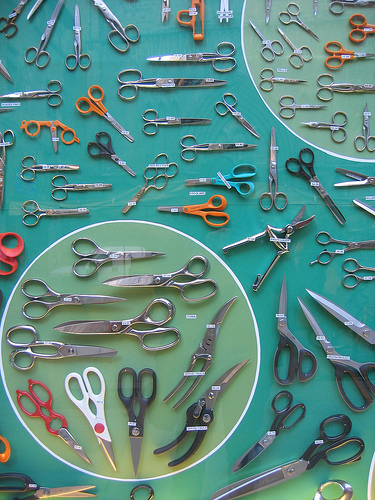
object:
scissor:
[177, 133, 257, 164]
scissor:
[113, 63, 228, 107]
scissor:
[87, 0, 143, 56]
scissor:
[86, 132, 137, 179]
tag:
[217, 169, 231, 192]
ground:
[324, 113, 325, 136]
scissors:
[101, 253, 219, 304]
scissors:
[47, 173, 113, 202]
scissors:
[20, 195, 89, 227]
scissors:
[66, 236, 168, 280]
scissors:
[258, 126, 289, 217]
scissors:
[19, 118, 79, 154]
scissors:
[18, 154, 80, 182]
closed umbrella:
[150, 191, 230, 231]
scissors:
[140, 107, 209, 141]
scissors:
[116, 64, 234, 102]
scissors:
[159, 294, 236, 413]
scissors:
[213, 90, 261, 141]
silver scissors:
[332, 164, 375, 197]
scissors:
[72, 83, 135, 145]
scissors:
[19, 112, 80, 155]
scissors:
[322, 35, 375, 73]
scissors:
[256, 115, 287, 215]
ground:
[320, 125, 349, 168]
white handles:
[82, 363, 113, 410]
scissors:
[70, 237, 167, 279]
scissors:
[259, 123, 287, 213]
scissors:
[116, 67, 226, 102]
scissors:
[21, 279, 128, 321]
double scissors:
[120, 151, 179, 216]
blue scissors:
[183, 163, 257, 198]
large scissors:
[210, 414, 366, 499]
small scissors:
[228, 385, 306, 472]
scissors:
[347, 13, 372, 49]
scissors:
[172, 0, 208, 42]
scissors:
[272, 268, 318, 386]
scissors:
[299, 110, 349, 144]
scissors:
[156, 195, 234, 225]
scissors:
[178, 132, 258, 162]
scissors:
[285, 147, 348, 225]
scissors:
[246, 20, 285, 66]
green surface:
[245, 96, 267, 127]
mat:
[0, 0, 374, 499]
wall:
[145, 63, 184, 97]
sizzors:
[259, 127, 288, 213]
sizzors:
[212, 92, 265, 139]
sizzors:
[140, 107, 211, 139]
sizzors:
[144, 41, 237, 73]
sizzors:
[279, 93, 329, 120]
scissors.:
[276, 26, 315, 70]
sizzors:
[47, 171, 113, 202]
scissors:
[0, 471, 99, 498]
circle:
[93, 421, 105, 435]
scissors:
[57, 360, 127, 467]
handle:
[64, 370, 93, 420]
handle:
[13, 388, 50, 428]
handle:
[212, 179, 257, 198]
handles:
[206, 179, 256, 199]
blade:
[205, 295, 239, 335]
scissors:
[16, 378, 89, 471]